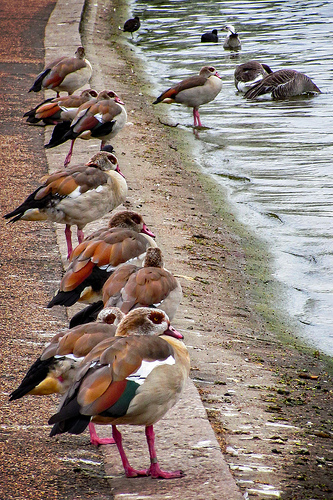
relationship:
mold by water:
[187, 161, 312, 354] [249, 105, 329, 222]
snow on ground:
[243, 432, 275, 458] [209, 375, 308, 496]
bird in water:
[0, 46, 220, 439] [249, 105, 329, 222]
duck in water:
[230, 59, 317, 96] [249, 105, 329, 222]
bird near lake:
[0, 46, 220, 439] [237, 101, 314, 174]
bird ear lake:
[0, 46, 220, 439] [237, 101, 314, 174]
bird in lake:
[0, 46, 220, 439] [237, 101, 314, 174]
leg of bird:
[169, 111, 225, 139] [0, 46, 220, 439]